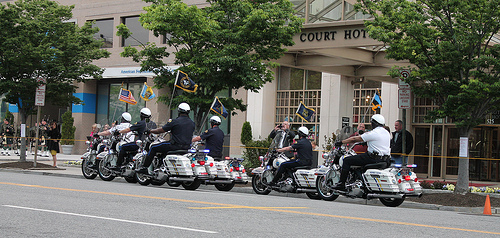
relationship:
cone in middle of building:
[484, 195, 493, 215] [83, 0, 493, 218]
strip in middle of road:
[92, 178, 202, 221] [0, 160, 500, 238]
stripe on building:
[1, 86, 96, 116] [2, 2, 483, 173]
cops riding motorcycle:
[329, 115, 395, 192] [311, 136, 429, 210]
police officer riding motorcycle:
[265, 120, 319, 187] [246, 142, 336, 197]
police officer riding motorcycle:
[128, 101, 200, 175] [123, 129, 220, 192]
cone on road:
[471, 179, 484, 219] [4, 160, 484, 232]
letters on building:
[298, 26, 370, 44] [62, 1, 482, 184]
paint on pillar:
[70, 90, 95, 113] [71, 82, 97, 152]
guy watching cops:
[388, 116, 417, 162] [72, 98, 421, 208]